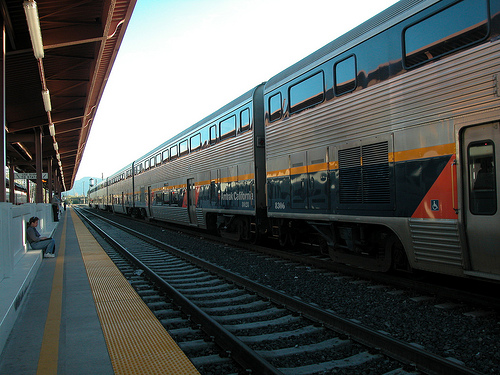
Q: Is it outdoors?
A: Yes, it is outdoors.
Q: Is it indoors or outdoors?
A: It is outdoors.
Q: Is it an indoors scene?
A: No, it is outdoors.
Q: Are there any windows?
A: Yes, there is a window.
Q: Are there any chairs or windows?
A: Yes, there is a window.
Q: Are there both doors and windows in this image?
A: Yes, there are both a window and a door.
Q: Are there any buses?
A: No, there are no buses.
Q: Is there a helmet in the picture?
A: No, there are no helmets.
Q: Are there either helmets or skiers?
A: No, there are no helmets or skiers.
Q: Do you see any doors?
A: Yes, there is a door.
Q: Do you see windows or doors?
A: Yes, there is a door.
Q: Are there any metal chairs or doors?
A: Yes, there is a metal door.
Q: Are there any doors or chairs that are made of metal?
A: Yes, the door is made of metal.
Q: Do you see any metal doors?
A: Yes, there is a metal door.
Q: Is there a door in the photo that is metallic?
A: Yes, there is a door that is metallic.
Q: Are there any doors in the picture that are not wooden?
A: Yes, there is a metallic door.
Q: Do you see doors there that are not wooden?
A: Yes, there is a metallic door.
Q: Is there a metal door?
A: Yes, there is a door that is made of metal.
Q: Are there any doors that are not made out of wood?
A: Yes, there is a door that is made of metal.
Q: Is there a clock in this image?
A: No, there are no clocks.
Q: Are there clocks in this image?
A: No, there are no clocks.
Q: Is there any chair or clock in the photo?
A: No, there are no clocks or chairs.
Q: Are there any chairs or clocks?
A: No, there are no clocks or chairs.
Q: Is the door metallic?
A: Yes, the door is metallic.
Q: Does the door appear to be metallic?
A: Yes, the door is metallic.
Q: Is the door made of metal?
A: Yes, the door is made of metal.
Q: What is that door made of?
A: The door is made of metal.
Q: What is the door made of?
A: The door is made of metal.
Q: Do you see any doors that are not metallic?
A: No, there is a door but it is metallic.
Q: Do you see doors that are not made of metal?
A: No, there is a door but it is made of metal.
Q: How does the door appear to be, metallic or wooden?
A: The door is metallic.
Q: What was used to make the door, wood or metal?
A: The door is made of metal.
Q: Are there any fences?
A: No, there are no fences.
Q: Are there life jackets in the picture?
A: No, there are no life jackets.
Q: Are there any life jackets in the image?
A: No, there are no life jackets.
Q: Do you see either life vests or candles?
A: No, there are no life vests or candles.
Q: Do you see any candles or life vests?
A: No, there are no life vests or candles.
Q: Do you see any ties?
A: Yes, there is a tie.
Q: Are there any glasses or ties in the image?
A: Yes, there is a tie.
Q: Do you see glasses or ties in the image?
A: Yes, there is a tie.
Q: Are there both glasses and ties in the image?
A: No, there is a tie but no glasses.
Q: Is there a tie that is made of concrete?
A: Yes, there is a tie that is made of concrete.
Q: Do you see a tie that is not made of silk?
A: Yes, there is a tie that is made of concrete.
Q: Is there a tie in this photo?
A: Yes, there is a tie.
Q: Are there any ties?
A: Yes, there is a tie.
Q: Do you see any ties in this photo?
A: Yes, there is a tie.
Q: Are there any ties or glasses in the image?
A: Yes, there is a tie.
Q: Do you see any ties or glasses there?
A: Yes, there is a tie.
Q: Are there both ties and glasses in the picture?
A: No, there is a tie but no glasses.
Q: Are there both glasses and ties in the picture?
A: No, there is a tie but no glasses.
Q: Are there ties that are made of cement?
A: Yes, there is a tie that is made of cement.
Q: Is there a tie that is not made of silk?
A: Yes, there is a tie that is made of concrete.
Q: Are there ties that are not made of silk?
A: Yes, there is a tie that is made of concrete.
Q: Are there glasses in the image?
A: No, there are no glasses.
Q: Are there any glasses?
A: No, there are no glasses.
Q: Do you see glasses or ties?
A: Yes, there is a tie.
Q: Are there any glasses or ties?
A: Yes, there is a tie.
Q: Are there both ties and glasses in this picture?
A: No, there is a tie but no glasses.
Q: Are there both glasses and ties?
A: No, there is a tie but no glasses.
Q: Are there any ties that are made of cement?
A: Yes, there is a tie that is made of cement.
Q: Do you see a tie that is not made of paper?
A: Yes, there is a tie that is made of cement.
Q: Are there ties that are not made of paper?
A: Yes, there is a tie that is made of cement.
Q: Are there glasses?
A: No, there are no glasses.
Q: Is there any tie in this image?
A: Yes, there is a tie.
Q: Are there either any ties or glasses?
A: Yes, there is a tie.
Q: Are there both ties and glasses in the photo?
A: No, there is a tie but no glasses.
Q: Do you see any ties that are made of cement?
A: Yes, there is a tie that is made of cement.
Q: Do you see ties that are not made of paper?
A: Yes, there is a tie that is made of concrete.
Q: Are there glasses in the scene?
A: No, there are no glasses.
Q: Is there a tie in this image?
A: Yes, there is a tie.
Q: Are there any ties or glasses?
A: Yes, there is a tie.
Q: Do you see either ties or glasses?
A: Yes, there is a tie.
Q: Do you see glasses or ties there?
A: Yes, there is a tie.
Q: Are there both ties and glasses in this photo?
A: No, there is a tie but no glasses.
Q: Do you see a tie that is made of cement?
A: Yes, there is a tie that is made of cement.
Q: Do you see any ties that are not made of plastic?
A: Yes, there is a tie that is made of cement.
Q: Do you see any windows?
A: Yes, there is a window.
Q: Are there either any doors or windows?
A: Yes, there is a window.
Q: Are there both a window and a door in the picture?
A: Yes, there are both a window and a door.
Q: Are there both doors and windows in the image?
A: Yes, there are both a window and doors.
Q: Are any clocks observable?
A: No, there are no clocks.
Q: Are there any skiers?
A: No, there are no skiers.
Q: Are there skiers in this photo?
A: No, there are no skiers.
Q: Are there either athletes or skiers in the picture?
A: No, there are no skiers or athletes.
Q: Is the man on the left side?
A: Yes, the man is on the left of the image.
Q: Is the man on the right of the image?
A: No, the man is on the left of the image.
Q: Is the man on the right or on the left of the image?
A: The man is on the left of the image.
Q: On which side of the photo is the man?
A: The man is on the left of the image.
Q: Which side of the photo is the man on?
A: The man is on the left of the image.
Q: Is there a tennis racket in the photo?
A: No, there are no rackets.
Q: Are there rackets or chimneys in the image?
A: No, there are no rackets or chimneys.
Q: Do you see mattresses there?
A: No, there are no mattresses.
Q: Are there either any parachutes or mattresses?
A: No, there are no mattresses or parachutes.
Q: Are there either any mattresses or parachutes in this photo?
A: No, there are no mattresses or parachutes.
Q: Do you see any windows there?
A: Yes, there are windows.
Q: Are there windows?
A: Yes, there are windows.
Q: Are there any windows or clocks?
A: Yes, there are windows.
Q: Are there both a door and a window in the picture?
A: Yes, there are both a window and a door.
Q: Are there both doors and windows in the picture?
A: Yes, there are both windows and a door.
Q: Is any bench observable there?
A: Yes, there is a bench.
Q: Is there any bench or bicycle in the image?
A: Yes, there is a bench.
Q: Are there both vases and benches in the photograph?
A: No, there is a bench but no vases.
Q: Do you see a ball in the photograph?
A: No, there are no balls.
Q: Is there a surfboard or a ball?
A: No, there are no balls or surfboards.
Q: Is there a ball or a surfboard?
A: No, there are no balls or surfboards.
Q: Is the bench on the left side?
A: Yes, the bench is on the left of the image.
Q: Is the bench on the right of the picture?
A: No, the bench is on the left of the image.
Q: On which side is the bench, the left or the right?
A: The bench is on the left of the image.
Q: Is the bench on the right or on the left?
A: The bench is on the left of the image.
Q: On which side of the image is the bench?
A: The bench is on the left of the image.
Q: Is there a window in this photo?
A: Yes, there is a window.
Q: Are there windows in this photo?
A: Yes, there is a window.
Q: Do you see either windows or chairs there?
A: Yes, there is a window.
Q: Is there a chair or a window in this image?
A: Yes, there is a window.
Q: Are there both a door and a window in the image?
A: Yes, there are both a window and a door.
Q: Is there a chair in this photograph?
A: No, there are no chairs.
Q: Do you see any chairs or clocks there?
A: No, there are no chairs or clocks.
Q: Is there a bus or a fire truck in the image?
A: No, there are no buses or fire trucks.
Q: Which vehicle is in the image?
A: The vehicle is a train car.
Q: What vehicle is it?
A: The vehicle is a train car.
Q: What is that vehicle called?
A: This is a train car.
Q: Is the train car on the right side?
A: Yes, the train car is on the right of the image.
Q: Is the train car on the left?
A: No, the train car is on the right of the image.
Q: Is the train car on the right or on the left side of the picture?
A: The train car is on the right of the image.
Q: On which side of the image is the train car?
A: The train car is on the right of the image.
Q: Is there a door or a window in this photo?
A: Yes, there is a window.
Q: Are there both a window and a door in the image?
A: Yes, there are both a window and a door.